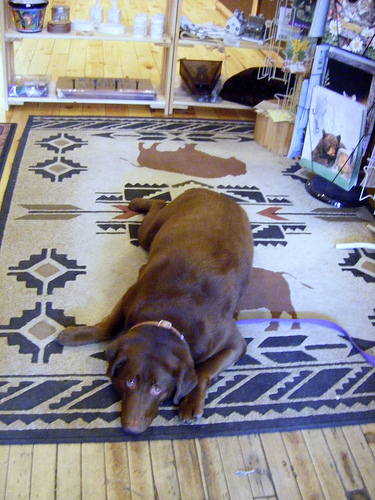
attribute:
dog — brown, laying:
[54, 169, 245, 439]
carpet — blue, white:
[18, 105, 171, 184]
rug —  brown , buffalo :
[1, 114, 370, 439]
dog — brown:
[58, 154, 259, 444]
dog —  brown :
[100, 176, 254, 443]